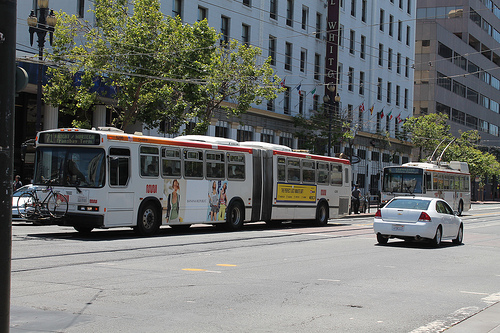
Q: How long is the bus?
A: Very long.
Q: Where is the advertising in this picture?
A: Side of the bus.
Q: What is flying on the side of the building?
A: Flags.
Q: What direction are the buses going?
A: Left.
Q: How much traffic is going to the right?
A: 1 car.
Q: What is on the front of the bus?
A: Bike.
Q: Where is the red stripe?
A: Top of the bus.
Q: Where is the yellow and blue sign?
A: Side of the bus.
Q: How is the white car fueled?
A: Gasoline.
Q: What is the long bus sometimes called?
A: Accordion bus.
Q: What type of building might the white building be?
A: Hotel.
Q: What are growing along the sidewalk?
A: Trees.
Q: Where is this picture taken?
A: On a city road.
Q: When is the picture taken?
A: During the day.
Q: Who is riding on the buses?
A: People.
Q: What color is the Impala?
A: White.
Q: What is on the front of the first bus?
A: A bicycle.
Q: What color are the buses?
A: White.